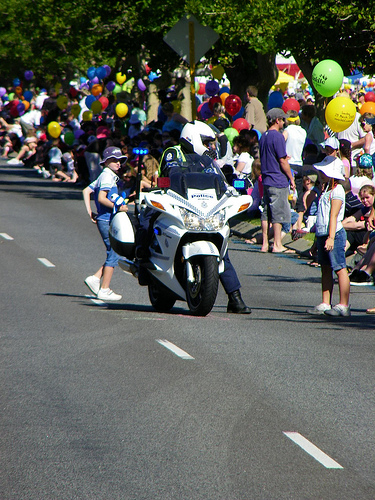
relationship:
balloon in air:
[311, 58, 343, 99] [246, 61, 363, 118]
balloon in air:
[311, 58, 343, 99] [220, 36, 360, 163]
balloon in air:
[324, 95, 357, 132] [220, 36, 360, 163]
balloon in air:
[311, 58, 343, 99] [248, 26, 363, 161]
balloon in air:
[94, 63, 118, 89] [260, 38, 362, 147]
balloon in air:
[311, 58, 343, 99] [260, 38, 362, 147]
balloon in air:
[311, 58, 343, 96] [255, 48, 364, 167]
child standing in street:
[312, 136, 358, 327] [50, 198, 363, 410]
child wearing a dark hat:
[81, 146, 123, 299] [97, 146, 126, 162]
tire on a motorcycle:
[137, 290, 175, 305] [83, 141, 236, 314]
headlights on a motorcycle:
[177, 205, 235, 233] [127, 161, 255, 318]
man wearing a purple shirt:
[248, 94, 310, 255] [257, 127, 291, 190]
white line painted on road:
[282, 428, 345, 469] [0, 154, 373, 497]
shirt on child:
[308, 185, 360, 249] [309, 155, 356, 323]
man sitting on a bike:
[125, 107, 251, 208] [108, 190, 252, 316]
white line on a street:
[282, 428, 345, 469] [18, 230, 310, 469]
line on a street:
[155, 337, 195, 359] [18, 230, 310, 469]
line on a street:
[85, 294, 104, 303] [18, 230, 310, 469]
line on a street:
[36, 256, 55, 266] [18, 230, 310, 469]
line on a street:
[0, 232, 13, 240] [18, 230, 310, 469]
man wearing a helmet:
[156, 120, 253, 315] [180, 120, 216, 157]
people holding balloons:
[16, 62, 142, 182] [310, 55, 356, 137]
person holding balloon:
[103, 121, 148, 145] [36, 107, 66, 134]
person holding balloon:
[80, 123, 111, 148] [104, 66, 138, 87]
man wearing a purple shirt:
[258, 106, 297, 253] [257, 127, 291, 191]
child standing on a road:
[306, 153, 356, 319] [0, 154, 373, 497]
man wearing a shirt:
[258, 106, 297, 253] [256, 129, 288, 185]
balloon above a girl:
[311, 58, 343, 99] [312, 158, 350, 317]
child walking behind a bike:
[82, 147, 129, 302] [108, 190, 252, 316]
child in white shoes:
[82, 147, 129, 302] [85, 271, 119, 308]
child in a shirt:
[82, 147, 129, 302] [89, 167, 121, 191]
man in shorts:
[258, 106, 297, 253] [260, 182, 291, 223]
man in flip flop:
[258, 106, 297, 253] [270, 246, 297, 253]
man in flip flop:
[258, 106, 297, 253] [258, 247, 271, 252]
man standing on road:
[258, 106, 297, 253] [0, 154, 373, 497]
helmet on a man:
[180, 120, 216, 157] [156, 120, 253, 315]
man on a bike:
[156, 120, 253, 315] [108, 190, 252, 316]